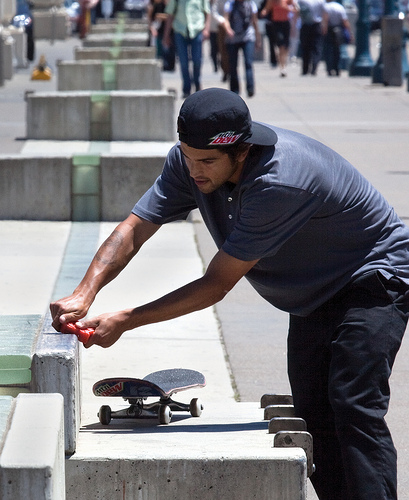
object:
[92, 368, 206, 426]
skate board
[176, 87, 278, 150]
hat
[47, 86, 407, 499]
man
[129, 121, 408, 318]
shirt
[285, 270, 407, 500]
pants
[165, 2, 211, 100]
people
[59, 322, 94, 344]
object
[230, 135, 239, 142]
letters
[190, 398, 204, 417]
wheel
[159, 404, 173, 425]
wheel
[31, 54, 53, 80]
object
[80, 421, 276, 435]
shadow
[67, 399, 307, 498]
concrete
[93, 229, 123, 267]
tattoo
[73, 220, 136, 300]
forearm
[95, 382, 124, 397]
company name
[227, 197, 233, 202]
button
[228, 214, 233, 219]
button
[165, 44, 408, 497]
sidewalk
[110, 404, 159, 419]
axel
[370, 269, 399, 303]
pocket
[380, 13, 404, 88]
pole